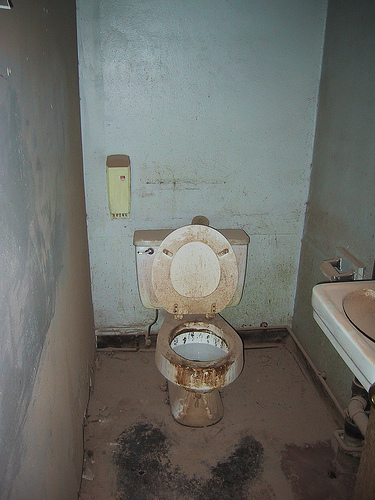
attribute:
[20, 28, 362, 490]
bathroom — DISGUSTING, DIRTY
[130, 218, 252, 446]
toilet — WHITE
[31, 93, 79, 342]
walls — DIRTY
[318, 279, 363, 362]
sink — DIRTY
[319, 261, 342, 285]
paper — TOILET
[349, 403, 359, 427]
pipe — DUSTY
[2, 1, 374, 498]
walls — gray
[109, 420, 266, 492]
spots — black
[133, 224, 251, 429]
toilet — untidy, very dirty, little dirty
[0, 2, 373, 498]
wall — dirty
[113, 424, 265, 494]
spot — black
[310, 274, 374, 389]
sink — dirty, white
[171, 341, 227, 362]
water — clear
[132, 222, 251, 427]
bathroom toilet — dirty, public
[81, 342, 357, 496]
bathroom floor — dirty